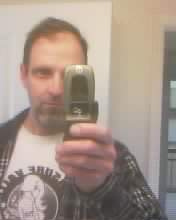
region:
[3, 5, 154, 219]
A man with a cell phone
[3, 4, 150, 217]
A man holding a flip phone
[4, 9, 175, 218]
A man wearing a t-shirt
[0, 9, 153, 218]
A man wearing a plaid shirt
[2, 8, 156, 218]
A man with a black and white shirt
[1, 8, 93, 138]
A man with a small beard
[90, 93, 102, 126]
Antenna on a flip phone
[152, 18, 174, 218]
Edge of a doorway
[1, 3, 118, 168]
White door behind a man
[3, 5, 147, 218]
Man looking at a cell phone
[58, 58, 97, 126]
Cell phone being used as a camera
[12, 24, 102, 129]
Man taking picture of himself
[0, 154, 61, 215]
Design printed on a teacher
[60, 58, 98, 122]
Back of a cell phone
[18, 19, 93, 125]
Man looking at a cell phone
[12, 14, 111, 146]
Man using his cell phone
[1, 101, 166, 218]
Long sleeved flannel shirt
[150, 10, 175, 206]
Doorway to adjoining room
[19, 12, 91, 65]
Receding hairline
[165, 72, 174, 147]
Windows in an adjoining room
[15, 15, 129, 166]
man holding a phone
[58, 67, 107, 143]
phone is flipped up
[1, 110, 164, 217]
man's shirt is plaid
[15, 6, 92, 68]
man's hair is brown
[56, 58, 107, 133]
phone is gray and black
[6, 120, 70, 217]
man's shirt is white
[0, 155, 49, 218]
character on front of man's shirt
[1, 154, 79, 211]
brown letters on man's shirt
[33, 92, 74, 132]
man has a beard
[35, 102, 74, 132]
man's beard is black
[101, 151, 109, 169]
edge of a fist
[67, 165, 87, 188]
part of a finger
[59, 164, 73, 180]
edge of a finger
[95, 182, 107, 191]
edge of a sleeve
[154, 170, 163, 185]
edge of a wall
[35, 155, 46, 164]
part of a t shirt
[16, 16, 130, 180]
Man holding cell phone.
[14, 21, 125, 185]
Man looking at phone.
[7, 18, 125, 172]
Phone is older model.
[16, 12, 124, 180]
Phone is a flip style.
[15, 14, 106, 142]
The man has hair.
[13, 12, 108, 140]
Man's hair is short.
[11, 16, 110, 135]
Man has a beard.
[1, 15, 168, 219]
Man is wearing shirt.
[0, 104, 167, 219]
The shirt is checkered.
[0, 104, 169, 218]
Man's shirt is black and white.